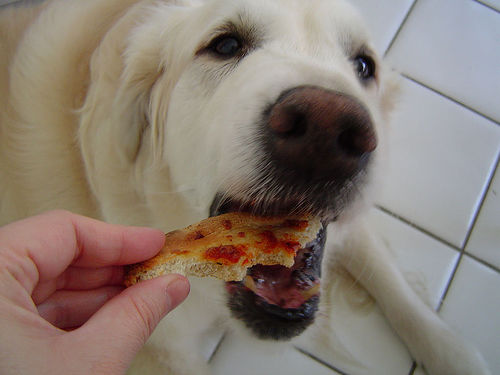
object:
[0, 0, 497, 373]
dog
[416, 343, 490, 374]
paw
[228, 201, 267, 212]
tongue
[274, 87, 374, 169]
nose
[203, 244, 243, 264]
sauce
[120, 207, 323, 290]
pizza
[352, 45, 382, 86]
eye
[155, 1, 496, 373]
floor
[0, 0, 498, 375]
room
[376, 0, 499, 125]
tiles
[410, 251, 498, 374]
tiles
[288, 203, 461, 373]
tiles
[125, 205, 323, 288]
pizza crust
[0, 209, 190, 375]
hand